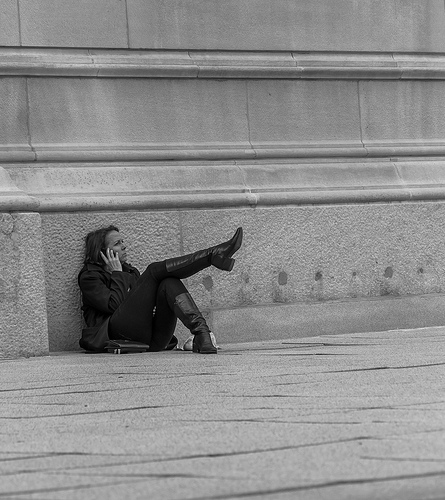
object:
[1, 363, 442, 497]
sidewalk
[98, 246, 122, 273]
hand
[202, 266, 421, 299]
spots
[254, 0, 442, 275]
wall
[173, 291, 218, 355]
boot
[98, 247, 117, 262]
cell phone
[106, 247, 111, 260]
finger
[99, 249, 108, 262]
finger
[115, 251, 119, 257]
finger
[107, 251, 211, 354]
legs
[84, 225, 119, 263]
hair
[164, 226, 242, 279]
boot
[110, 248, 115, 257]
finger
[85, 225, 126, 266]
head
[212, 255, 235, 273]
heel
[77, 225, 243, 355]
female